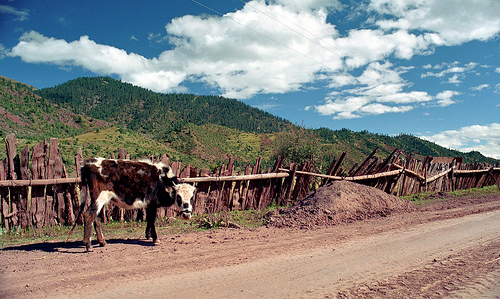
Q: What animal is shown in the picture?
A: A cow.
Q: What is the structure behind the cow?
A: A fence.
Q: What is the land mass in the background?
A: Hills.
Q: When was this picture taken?
A: Daylight.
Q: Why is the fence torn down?
A: Needs repair.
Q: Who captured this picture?
A: Photographer.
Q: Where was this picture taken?
A: On a farm.